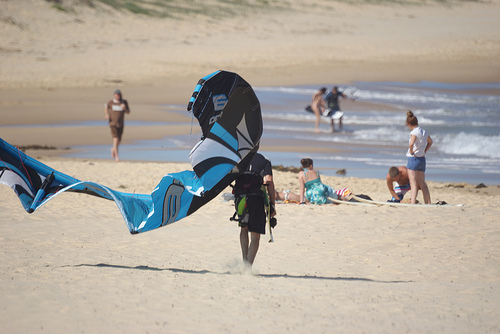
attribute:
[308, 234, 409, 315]
shore — light, sandy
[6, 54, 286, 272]
parasail — large, blue, black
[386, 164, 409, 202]
man — shirtless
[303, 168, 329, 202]
swimsuit — green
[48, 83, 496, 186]
water — ocean water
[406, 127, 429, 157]
shirt — white